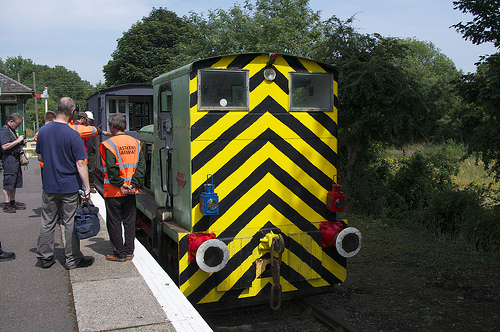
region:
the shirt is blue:
[35, 112, 87, 201]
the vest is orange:
[90, 131, 157, 203]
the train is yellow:
[179, 40, 366, 330]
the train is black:
[167, 35, 367, 328]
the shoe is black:
[62, 255, 96, 273]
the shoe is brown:
[101, 245, 133, 265]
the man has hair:
[112, 116, 127, 129]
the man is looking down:
[5, 107, 30, 207]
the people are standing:
[0, 83, 147, 268]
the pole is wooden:
[25, 64, 43, 125]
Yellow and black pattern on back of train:
[248, 76, 290, 232]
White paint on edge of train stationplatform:
[136, 257, 203, 329]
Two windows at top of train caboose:
[195, 67, 337, 117]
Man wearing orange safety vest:
[92, 110, 155, 266]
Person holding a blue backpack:
[36, 115, 108, 246]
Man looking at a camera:
[3, 110, 30, 199]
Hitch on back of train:
[258, 230, 298, 307]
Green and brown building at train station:
[3, 71, 35, 133]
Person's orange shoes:
[106, 237, 138, 267]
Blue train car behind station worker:
[86, 85, 159, 156]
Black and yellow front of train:
[180, 58, 352, 289]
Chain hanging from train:
[266, 226, 295, 318]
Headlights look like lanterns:
[196, 171, 349, 217]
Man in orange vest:
[96, 127, 151, 204]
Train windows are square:
[184, 64, 341, 119]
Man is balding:
[36, 88, 88, 123]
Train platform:
[3, 123, 207, 328]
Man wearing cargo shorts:
[0, 110, 29, 213]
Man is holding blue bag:
[67, 182, 107, 242]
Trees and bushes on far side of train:
[338, 27, 491, 272]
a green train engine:
[125, 44, 354, 307]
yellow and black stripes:
[185, 55, 346, 295]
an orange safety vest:
[97, 130, 137, 197]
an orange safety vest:
[69, 116, 95, 146]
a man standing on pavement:
[35, 95, 92, 276]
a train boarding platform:
[2, 150, 206, 329]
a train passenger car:
[80, 82, 152, 167]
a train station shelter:
[0, 62, 35, 121]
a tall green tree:
[102, 6, 199, 95]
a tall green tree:
[392, 35, 460, 140]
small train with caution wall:
[113, 11, 377, 318]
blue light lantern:
[170, 165, 253, 237]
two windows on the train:
[151, 33, 371, 153]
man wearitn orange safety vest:
[85, 94, 158, 270]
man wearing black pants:
[82, 80, 165, 276]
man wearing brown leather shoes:
[62, 98, 157, 281]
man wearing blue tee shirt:
[15, 80, 120, 281]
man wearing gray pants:
[26, 88, 87, 280]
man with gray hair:
[25, 91, 92, 297]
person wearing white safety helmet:
[57, 98, 112, 175]